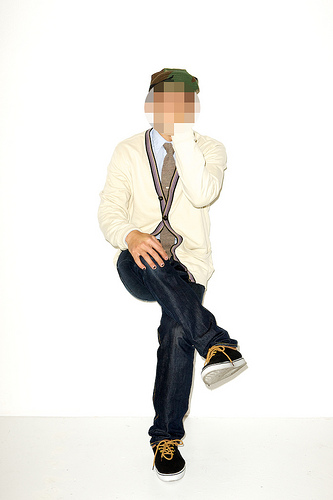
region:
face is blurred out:
[143, 75, 207, 149]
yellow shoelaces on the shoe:
[145, 437, 194, 481]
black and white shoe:
[142, 437, 192, 482]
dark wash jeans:
[110, 243, 238, 446]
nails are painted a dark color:
[129, 254, 178, 270]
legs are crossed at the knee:
[116, 249, 261, 480]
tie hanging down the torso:
[156, 143, 183, 263]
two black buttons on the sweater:
[157, 195, 172, 222]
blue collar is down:
[149, 132, 166, 151]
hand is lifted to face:
[166, 91, 195, 151]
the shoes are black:
[130, 312, 248, 483]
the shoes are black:
[124, 393, 211, 488]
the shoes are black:
[178, 328, 260, 405]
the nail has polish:
[130, 251, 151, 275]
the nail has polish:
[147, 258, 160, 282]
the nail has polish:
[159, 260, 168, 272]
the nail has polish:
[130, 248, 164, 288]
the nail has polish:
[138, 254, 155, 270]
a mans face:
[144, 81, 201, 136]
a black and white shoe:
[147, 434, 189, 482]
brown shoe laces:
[152, 437, 181, 459]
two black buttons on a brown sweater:
[154, 193, 172, 222]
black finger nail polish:
[139, 264, 159, 271]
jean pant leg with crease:
[147, 342, 196, 435]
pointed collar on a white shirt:
[150, 127, 164, 157]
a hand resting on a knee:
[127, 230, 169, 271]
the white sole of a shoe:
[202, 359, 250, 388]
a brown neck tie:
[161, 144, 175, 197]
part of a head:
[162, 91, 177, 114]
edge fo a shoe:
[159, 465, 177, 484]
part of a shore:
[217, 441, 230, 459]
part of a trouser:
[149, 416, 175, 453]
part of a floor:
[240, 417, 257, 439]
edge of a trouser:
[180, 405, 187, 418]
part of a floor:
[224, 450, 233, 471]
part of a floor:
[240, 452, 259, 484]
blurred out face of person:
[143, 78, 207, 129]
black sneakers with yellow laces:
[142, 438, 197, 480]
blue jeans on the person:
[117, 255, 217, 348]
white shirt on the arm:
[107, 148, 137, 216]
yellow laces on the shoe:
[145, 435, 188, 461]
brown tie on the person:
[156, 139, 177, 193]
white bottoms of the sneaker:
[199, 364, 259, 386]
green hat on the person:
[139, 62, 203, 87]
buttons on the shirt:
[156, 187, 175, 230]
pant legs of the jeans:
[203, 334, 237, 348]